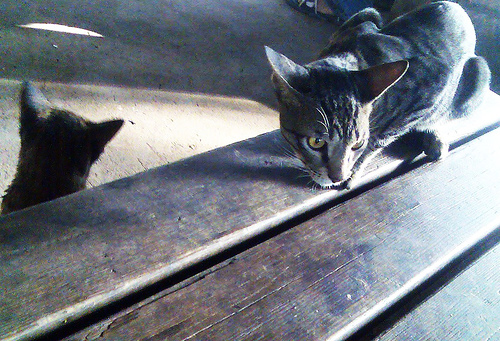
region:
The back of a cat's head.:
[1, 78, 123, 211]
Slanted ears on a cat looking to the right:
[263, 43, 408, 100]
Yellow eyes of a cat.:
[306, 133, 366, 153]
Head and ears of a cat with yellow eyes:
[263, 45, 410, 186]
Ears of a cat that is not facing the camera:
[21, 80, 125, 150]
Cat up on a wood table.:
[266, 0, 492, 187]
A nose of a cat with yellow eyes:
[326, 147, 349, 182]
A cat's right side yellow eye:
[306, 133, 326, 153]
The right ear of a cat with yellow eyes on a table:
[262, 44, 309, 94]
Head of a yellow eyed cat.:
[294, 67, 370, 189]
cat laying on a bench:
[252, 10, 499, 192]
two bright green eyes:
[302, 128, 372, 158]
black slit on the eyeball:
[312, 135, 319, 148]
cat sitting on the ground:
[4, 75, 117, 217]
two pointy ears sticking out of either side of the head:
[14, 74, 141, 156]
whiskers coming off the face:
[272, 144, 346, 199]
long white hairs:
[309, 102, 336, 135]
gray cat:
[241, 0, 493, 205]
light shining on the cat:
[447, 3, 481, 105]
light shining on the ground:
[18, 13, 108, 45]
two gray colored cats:
[9, 11, 486, 191]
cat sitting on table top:
[8, 19, 498, 340]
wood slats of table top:
[16, 93, 498, 340]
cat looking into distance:
[2, 77, 106, 192]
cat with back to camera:
[2, 70, 106, 192]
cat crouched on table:
[264, 3, 483, 172]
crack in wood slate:
[77, 267, 281, 336]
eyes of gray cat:
[298, 130, 369, 162]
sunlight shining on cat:
[393, 18, 498, 280]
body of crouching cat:
[338, 0, 480, 122]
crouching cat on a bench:
[264, 1, 489, 188]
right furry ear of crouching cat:
[259, 46, 311, 108]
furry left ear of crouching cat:
[350, 57, 407, 104]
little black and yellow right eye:
[305, 131, 325, 147]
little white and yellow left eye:
[348, 135, 363, 152]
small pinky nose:
[328, 168, 351, 185]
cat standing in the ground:
[5, 75, 125, 202]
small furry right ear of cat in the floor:
[89, 115, 121, 156]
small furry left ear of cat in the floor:
[19, 77, 49, 135]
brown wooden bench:
[1, 78, 498, 336]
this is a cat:
[267, 0, 488, 180]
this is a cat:
[13, 85, 144, 191]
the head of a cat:
[5, 77, 136, 186]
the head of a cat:
[245, 50, 399, 190]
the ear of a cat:
[351, 55, 408, 97]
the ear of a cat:
[257, 46, 311, 103]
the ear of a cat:
[88, 110, 133, 147]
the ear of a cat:
[11, 78, 45, 120]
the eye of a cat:
[302, 128, 333, 158]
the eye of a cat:
[347, 132, 369, 156]